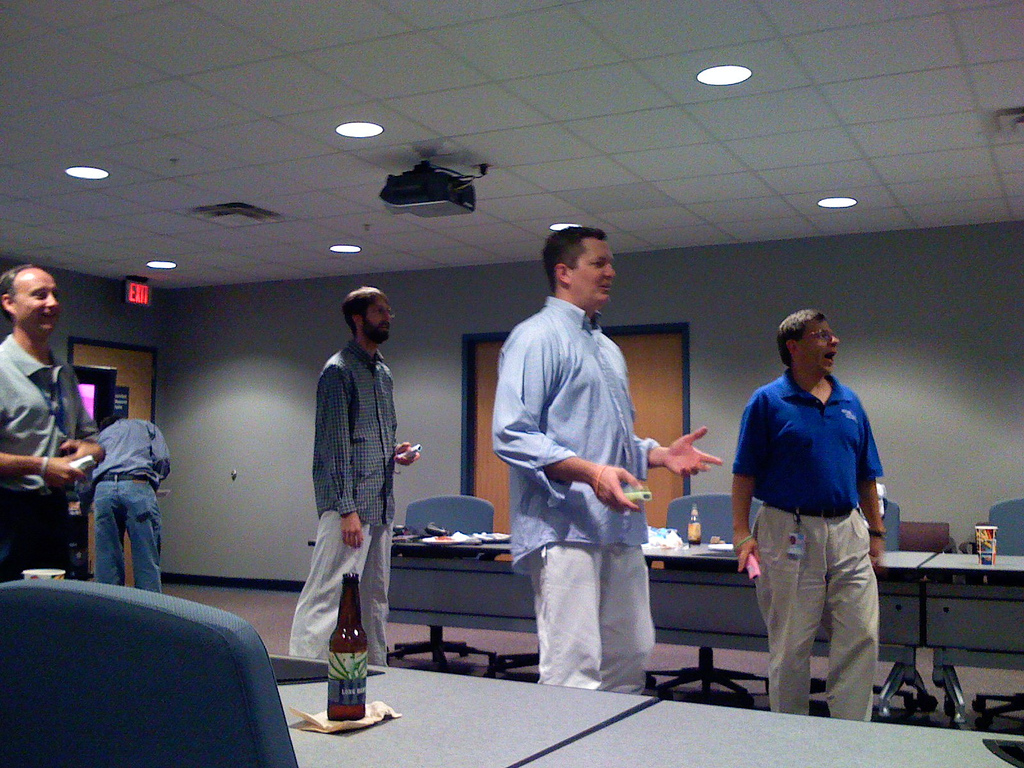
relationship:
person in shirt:
[731, 308, 887, 720] [732, 376, 881, 517]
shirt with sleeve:
[732, 376, 881, 517] [727, 381, 782, 485]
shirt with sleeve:
[732, 376, 881, 517] [847, 389, 887, 485]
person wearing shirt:
[731, 308, 887, 720] [732, 376, 881, 517]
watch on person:
[872, 528, 886, 541] [731, 308, 887, 720]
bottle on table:
[324, 570, 364, 720] [265, 654, 1021, 765]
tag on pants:
[787, 529, 801, 552] [752, 508, 880, 717]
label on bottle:
[322, 651, 365, 710] [325, 572, 369, 721]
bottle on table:
[325, 572, 369, 721] [265, 654, 1021, 765]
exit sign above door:
[128, 284, 150, 306] [72, 338, 161, 583]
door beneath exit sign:
[72, 338, 161, 583] [125, 279, 149, 308]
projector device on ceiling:
[381, 165, 476, 219] [17, 1, 985, 295]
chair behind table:
[6, 572, 295, 765] [265, 654, 1021, 765]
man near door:
[90, 420, 170, 592] [72, 338, 161, 583]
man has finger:
[490, 224, 728, 695] [687, 426, 708, 442]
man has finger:
[490, 224, 728, 695] [697, 448, 723, 465]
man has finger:
[490, 224, 728, 695] [615, 465, 638, 484]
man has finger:
[490, 224, 728, 695] [615, 488, 638, 509]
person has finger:
[287, 284, 421, 662] [347, 529, 360, 548]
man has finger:
[490, 224, 728, 695] [668, 458, 687, 475]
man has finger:
[490, 224, 728, 695] [676, 464, 697, 477]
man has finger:
[490, 224, 728, 695] [682, 459, 703, 472]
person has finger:
[732, 306, 887, 718] [734, 545, 752, 574]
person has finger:
[732, 306, 887, 718] [872, 551, 883, 569]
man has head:
[490, 223, 722, 701] [540, 221, 617, 313]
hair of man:
[546, 224, 610, 291] [490, 223, 722, 701]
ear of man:
[556, 271, 575, 285] [490, 223, 722, 701]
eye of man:
[579, 257, 614, 273] [490, 223, 722, 701]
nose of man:
[592, 266, 628, 279] [490, 223, 722, 701]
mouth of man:
[585, 277, 611, 300] [490, 223, 722, 701]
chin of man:
[573, 285, 634, 314] [490, 223, 722, 701]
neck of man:
[539, 289, 585, 319] [490, 223, 722, 701]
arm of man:
[484, 315, 614, 505] [490, 223, 722, 701]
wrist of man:
[554, 443, 596, 485] [490, 223, 722, 701]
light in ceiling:
[697, 59, 756, 94] [17, 1, 985, 295]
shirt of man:
[498, 285, 658, 579] [490, 223, 722, 701]